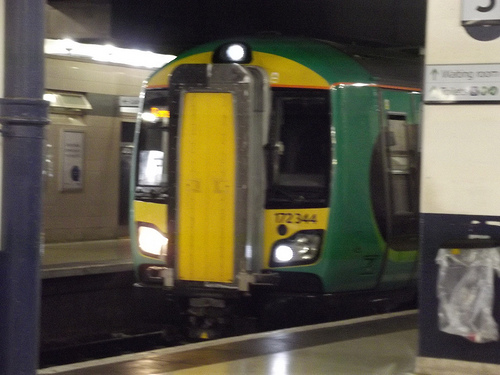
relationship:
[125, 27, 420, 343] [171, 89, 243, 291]
train has door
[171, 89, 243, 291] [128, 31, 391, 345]
door in front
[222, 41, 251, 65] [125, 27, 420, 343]
light on top of train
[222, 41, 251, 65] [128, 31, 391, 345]
light in front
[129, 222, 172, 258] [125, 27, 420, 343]
headlight on bottom of train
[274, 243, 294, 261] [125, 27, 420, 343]
headlight on bottom of train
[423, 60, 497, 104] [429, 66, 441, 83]
direction map has arrow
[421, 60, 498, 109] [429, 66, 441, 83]
direction map has arrow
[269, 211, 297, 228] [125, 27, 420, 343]
number on bottom of train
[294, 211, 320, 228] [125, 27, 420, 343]
number on bottom of train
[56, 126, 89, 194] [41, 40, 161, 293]
poster on wall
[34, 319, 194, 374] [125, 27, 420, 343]
train tracks are beneath train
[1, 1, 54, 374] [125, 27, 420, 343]
pole by train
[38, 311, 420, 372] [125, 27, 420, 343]
platform by train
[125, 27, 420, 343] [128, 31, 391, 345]
train has front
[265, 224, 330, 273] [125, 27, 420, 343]
headlight on train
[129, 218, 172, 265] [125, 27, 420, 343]
headlight on train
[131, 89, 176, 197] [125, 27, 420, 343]
windshield on train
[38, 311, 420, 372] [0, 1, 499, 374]
platform at train station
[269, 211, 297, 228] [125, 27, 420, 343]
number on train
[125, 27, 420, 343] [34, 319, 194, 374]
train on train tracks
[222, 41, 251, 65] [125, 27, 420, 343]
light on train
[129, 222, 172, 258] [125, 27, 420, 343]
headlight on train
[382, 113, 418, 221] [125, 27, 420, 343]
window on train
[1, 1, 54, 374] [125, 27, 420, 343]
pole near train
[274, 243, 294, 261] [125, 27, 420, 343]
headlight on train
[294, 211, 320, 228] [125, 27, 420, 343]
number on train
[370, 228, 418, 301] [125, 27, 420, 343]
ladder on train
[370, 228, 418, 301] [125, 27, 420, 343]
ladder on side of train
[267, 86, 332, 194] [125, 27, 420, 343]
windshield on train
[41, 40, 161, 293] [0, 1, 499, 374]
wall at train station